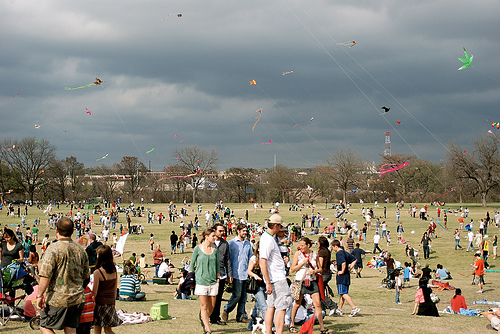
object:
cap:
[266, 212, 289, 229]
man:
[259, 210, 292, 333]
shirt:
[37, 238, 92, 307]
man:
[34, 217, 91, 334]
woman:
[117, 266, 147, 300]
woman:
[0, 227, 26, 310]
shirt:
[0, 241, 23, 269]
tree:
[0, 134, 58, 206]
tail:
[60, 83, 97, 91]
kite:
[63, 76, 106, 91]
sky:
[0, 0, 498, 172]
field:
[0, 201, 499, 334]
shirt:
[93, 264, 119, 306]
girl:
[91, 243, 124, 333]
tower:
[383, 130, 391, 159]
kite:
[453, 47, 476, 73]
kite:
[375, 160, 408, 177]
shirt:
[185, 243, 222, 285]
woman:
[187, 229, 220, 334]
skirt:
[93, 303, 123, 328]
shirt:
[76, 287, 94, 322]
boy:
[74, 278, 96, 333]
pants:
[35, 298, 87, 330]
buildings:
[76, 174, 147, 196]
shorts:
[335, 281, 349, 294]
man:
[326, 239, 360, 318]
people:
[447, 287, 466, 315]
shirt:
[259, 231, 288, 284]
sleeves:
[188, 243, 201, 274]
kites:
[247, 108, 265, 132]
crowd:
[0, 195, 499, 334]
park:
[0, 123, 499, 333]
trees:
[110, 155, 158, 205]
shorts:
[192, 281, 220, 297]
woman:
[409, 276, 441, 316]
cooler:
[146, 302, 171, 321]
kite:
[148, 164, 206, 185]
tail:
[150, 171, 194, 184]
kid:
[391, 267, 403, 303]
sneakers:
[396, 301, 403, 305]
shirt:
[448, 293, 466, 310]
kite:
[257, 138, 274, 146]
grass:
[0, 201, 498, 333]